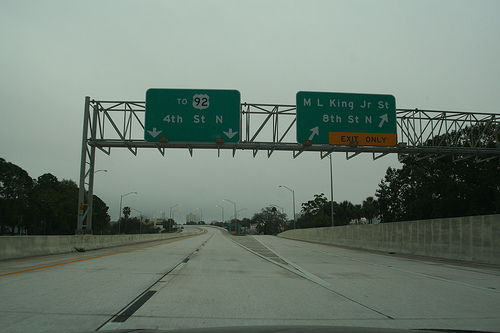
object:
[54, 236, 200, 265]
line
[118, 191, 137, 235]
street lights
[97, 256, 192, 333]
line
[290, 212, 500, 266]
barrier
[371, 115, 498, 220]
trees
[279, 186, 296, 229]
pole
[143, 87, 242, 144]
signs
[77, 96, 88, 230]
pole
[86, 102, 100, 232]
pole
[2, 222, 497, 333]
highway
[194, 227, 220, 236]
ramp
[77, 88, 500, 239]
structure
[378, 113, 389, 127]
white arrow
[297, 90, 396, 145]
green sign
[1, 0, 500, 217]
sky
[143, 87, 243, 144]
printing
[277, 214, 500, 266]
wall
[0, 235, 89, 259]
barrier